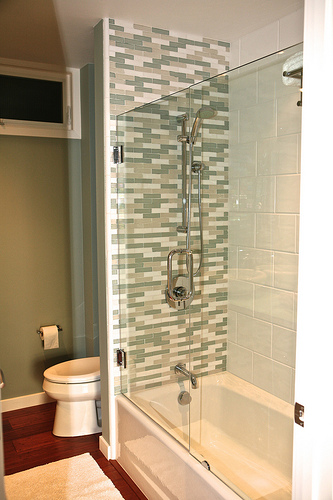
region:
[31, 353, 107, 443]
White toilet with seat up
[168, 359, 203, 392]
Silver faucet in bathtub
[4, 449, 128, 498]
White rug on bathroom floor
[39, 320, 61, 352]
Hanging roll of toilet paper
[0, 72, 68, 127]
Window in bath room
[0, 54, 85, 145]
White window frame of bathroom window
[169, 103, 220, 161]
Shower head in shower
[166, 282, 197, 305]
Hot and cold knob in shower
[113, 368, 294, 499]
White bathtub in bathroom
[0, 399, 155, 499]
brownish red bathroom floor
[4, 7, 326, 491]
A bathroom scene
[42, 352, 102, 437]
This is a commode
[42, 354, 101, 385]
The commode's lid is closed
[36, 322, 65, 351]
A roll of toilet paper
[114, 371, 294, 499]
This is a bath tub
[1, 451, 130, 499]
A rug is on the floor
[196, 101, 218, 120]
A shower head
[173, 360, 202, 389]
The bath tub faucet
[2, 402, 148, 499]
The floor is made of wood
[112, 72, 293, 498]
The shower door is glass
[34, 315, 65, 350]
roll of toilet paper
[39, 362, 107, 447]
toilet with the seat down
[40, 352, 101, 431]
white toilet with seat down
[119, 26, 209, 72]
mosaic tile pattern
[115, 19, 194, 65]
neutral gray and white tile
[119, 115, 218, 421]
glass shower door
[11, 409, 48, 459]
wood grain flooring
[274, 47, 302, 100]
white towel on silver rack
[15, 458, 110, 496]
white cotton towel on floor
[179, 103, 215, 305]
silver removable shower head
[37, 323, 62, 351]
a roll of toilet paper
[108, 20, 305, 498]
a glass shower door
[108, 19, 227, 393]
a tile wall inside a shower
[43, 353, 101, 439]
a white toilet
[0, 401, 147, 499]
a brown hardwood floor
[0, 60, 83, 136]
a window near the ceiling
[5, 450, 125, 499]
a towel mat on the floor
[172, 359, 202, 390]
a faucet in a shower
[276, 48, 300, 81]
a towel on a rack in a shower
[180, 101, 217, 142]
the shower head in a shower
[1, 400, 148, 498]
The floor is made of wood.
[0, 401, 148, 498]
The floor is brown.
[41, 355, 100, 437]
The toilet is white.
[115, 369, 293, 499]
The tub is white.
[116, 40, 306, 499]
The shower has glass doors.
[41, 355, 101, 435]
The toilet seat is down.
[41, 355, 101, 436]
The toilet lid is down.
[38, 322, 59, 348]
A roll of toilet paper.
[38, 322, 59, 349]
The toilet paper is white.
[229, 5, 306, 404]
The wall is white.